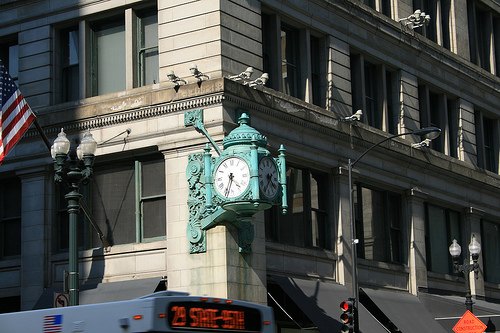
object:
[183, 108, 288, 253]
clock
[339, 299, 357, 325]
light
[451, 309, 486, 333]
sign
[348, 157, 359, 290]
pole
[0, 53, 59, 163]
flag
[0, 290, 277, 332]
bus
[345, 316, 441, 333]
street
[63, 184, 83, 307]
post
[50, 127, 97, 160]
light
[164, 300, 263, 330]
word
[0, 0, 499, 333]
building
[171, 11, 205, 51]
stone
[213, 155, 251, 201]
face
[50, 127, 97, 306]
lamp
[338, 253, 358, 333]
pole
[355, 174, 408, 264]
window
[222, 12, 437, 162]
wall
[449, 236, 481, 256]
light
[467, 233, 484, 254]
light